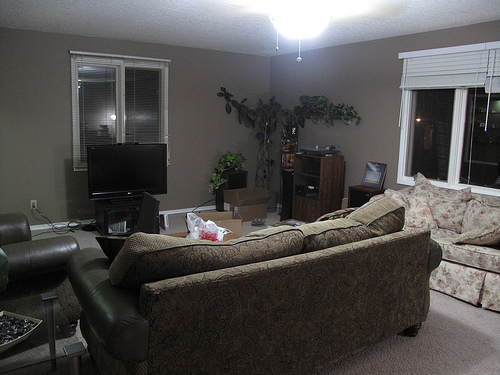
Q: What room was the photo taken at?
A: It was taken at the living room.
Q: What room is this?
A: It is a living room.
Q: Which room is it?
A: It is a living room.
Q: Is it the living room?
A: Yes, it is the living room.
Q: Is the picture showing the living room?
A: Yes, it is showing the living room.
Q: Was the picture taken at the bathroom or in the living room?
A: It was taken at the living room.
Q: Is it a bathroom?
A: No, it is a living room.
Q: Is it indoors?
A: Yes, it is indoors.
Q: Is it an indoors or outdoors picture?
A: It is indoors.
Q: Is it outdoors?
A: No, it is indoors.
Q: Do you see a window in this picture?
A: Yes, there is a window.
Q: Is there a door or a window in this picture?
A: Yes, there is a window.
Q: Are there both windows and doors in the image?
A: No, there is a window but no doors.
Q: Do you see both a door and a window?
A: No, there is a window but no doors.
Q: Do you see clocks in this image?
A: No, there are no clocks.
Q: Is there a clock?
A: No, there are no clocks.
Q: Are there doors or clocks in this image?
A: No, there are no clocks or doors.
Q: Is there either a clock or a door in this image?
A: No, there are no clocks or doors.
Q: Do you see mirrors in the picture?
A: No, there are no mirrors.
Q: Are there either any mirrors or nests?
A: No, there are no mirrors or nests.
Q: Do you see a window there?
A: Yes, there is a window.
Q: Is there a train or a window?
A: Yes, there is a window.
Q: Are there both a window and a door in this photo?
A: No, there is a window but no doors.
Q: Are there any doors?
A: No, there are no doors.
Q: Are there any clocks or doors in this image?
A: No, there are no doors or clocks.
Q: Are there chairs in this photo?
A: Yes, there is a chair.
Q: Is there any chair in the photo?
A: Yes, there is a chair.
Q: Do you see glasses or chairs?
A: Yes, there is a chair.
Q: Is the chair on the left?
A: Yes, the chair is on the left of the image.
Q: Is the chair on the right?
A: No, the chair is on the left of the image.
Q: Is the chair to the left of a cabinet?
A: No, the chair is to the left of a box.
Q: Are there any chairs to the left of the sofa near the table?
A: Yes, there is a chair to the left of the sofa.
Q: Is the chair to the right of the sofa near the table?
A: No, the chair is to the left of the sofa.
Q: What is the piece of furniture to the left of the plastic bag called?
A: The piece of furniture is a chair.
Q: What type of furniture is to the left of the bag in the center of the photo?
A: The piece of furniture is a chair.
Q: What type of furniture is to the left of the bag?
A: The piece of furniture is a chair.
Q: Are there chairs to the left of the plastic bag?
A: Yes, there is a chair to the left of the bag.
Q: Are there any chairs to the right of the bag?
A: No, the chair is to the left of the bag.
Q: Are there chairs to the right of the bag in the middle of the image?
A: No, the chair is to the left of the bag.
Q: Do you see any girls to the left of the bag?
A: No, there is a chair to the left of the bag.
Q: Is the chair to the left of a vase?
A: No, the chair is to the left of the bag.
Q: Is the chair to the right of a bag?
A: No, the chair is to the left of a bag.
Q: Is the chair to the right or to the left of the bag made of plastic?
A: The chair is to the left of the bag.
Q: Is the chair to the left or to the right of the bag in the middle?
A: The chair is to the left of the bag.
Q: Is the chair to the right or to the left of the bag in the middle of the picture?
A: The chair is to the left of the bag.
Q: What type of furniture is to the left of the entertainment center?
A: The piece of furniture is a chair.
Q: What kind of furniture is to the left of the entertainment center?
A: The piece of furniture is a chair.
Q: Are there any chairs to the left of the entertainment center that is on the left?
A: Yes, there is a chair to the left of the entertainment center.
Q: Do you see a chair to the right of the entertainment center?
A: No, the chair is to the left of the entertainment center.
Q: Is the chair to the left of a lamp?
A: No, the chair is to the left of the entertainment center.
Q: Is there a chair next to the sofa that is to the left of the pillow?
A: Yes, there is a chair next to the sofa.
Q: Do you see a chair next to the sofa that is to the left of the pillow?
A: Yes, there is a chair next to the sofa.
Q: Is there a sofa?
A: Yes, there is a sofa.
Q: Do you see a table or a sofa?
A: Yes, there is a sofa.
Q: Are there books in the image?
A: No, there are no books.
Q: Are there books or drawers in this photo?
A: No, there are no books or drawers.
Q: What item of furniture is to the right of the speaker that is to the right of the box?
A: The piece of furniture is a sofa.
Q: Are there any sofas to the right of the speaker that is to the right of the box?
A: Yes, there is a sofa to the right of the speaker.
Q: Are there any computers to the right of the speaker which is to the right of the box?
A: No, there is a sofa to the right of the speaker.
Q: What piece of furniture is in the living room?
A: The piece of furniture is a sofa.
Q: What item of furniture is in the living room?
A: The piece of furniture is a sofa.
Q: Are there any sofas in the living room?
A: Yes, there is a sofa in the living room.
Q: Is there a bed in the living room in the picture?
A: No, there is a sofa in the living room.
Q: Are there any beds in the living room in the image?
A: No, there is a sofa in the living room.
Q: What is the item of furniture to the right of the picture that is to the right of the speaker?
A: The piece of furniture is a sofa.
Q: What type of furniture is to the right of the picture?
A: The piece of furniture is a sofa.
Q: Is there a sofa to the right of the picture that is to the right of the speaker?
A: Yes, there is a sofa to the right of the picture.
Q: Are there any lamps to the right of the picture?
A: No, there is a sofa to the right of the picture.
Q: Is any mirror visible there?
A: No, there are no mirrors.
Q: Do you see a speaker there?
A: Yes, there is a speaker.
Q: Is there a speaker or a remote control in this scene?
A: Yes, there is a speaker.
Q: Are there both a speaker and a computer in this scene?
A: No, there is a speaker but no computers.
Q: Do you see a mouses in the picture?
A: No, there are no computer mousess.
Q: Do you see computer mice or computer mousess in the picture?
A: No, there are no computer mousess or computer mice.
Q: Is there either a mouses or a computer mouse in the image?
A: No, there are no computer mousess or computer mice.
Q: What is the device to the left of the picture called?
A: The device is a speaker.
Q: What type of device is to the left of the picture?
A: The device is a speaker.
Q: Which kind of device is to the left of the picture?
A: The device is a speaker.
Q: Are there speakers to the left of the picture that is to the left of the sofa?
A: Yes, there is a speaker to the left of the picture.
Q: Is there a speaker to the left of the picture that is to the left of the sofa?
A: Yes, there is a speaker to the left of the picture.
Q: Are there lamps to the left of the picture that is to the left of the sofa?
A: No, there is a speaker to the left of the picture.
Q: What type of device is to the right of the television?
A: The device is a speaker.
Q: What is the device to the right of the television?
A: The device is a speaker.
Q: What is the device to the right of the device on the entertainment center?
A: The device is a speaker.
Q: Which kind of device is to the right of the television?
A: The device is a speaker.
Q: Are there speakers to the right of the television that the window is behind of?
A: Yes, there is a speaker to the right of the TV.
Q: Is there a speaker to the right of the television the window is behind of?
A: Yes, there is a speaker to the right of the TV.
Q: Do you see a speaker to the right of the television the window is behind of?
A: Yes, there is a speaker to the right of the TV.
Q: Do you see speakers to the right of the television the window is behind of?
A: Yes, there is a speaker to the right of the TV.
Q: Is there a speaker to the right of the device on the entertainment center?
A: Yes, there is a speaker to the right of the TV.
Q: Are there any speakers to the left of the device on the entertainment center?
A: No, the speaker is to the right of the television.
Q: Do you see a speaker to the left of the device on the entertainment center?
A: No, the speaker is to the right of the television.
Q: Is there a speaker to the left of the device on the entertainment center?
A: No, the speaker is to the right of the television.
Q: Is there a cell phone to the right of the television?
A: No, there is a speaker to the right of the television.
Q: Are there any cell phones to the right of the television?
A: No, there is a speaker to the right of the television.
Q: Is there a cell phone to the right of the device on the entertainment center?
A: No, there is a speaker to the right of the television.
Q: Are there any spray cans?
A: No, there are no spray cans.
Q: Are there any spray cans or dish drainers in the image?
A: No, there are no spray cans or dish drainers.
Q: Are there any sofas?
A: Yes, there is a sofa.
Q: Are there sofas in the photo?
A: Yes, there is a sofa.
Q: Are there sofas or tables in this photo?
A: Yes, there is a sofa.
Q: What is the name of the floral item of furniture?
A: The piece of furniture is a sofa.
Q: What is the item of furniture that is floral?
A: The piece of furniture is a sofa.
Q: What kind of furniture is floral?
A: The furniture is a sofa.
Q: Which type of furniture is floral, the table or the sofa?
A: The sofa is floral.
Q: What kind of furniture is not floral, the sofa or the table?
A: The table is not floral.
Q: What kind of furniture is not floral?
A: The furniture is a table.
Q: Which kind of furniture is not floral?
A: The furniture is a table.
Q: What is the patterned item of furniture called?
A: The piece of furniture is a sofa.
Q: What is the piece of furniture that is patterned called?
A: The piece of furniture is a sofa.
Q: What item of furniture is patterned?
A: The piece of furniture is a sofa.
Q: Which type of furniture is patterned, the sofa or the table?
A: The sofa is patterned.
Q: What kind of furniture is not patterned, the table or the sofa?
A: The table is not patterned.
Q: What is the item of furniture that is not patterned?
A: The piece of furniture is a table.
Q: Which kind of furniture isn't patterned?
A: The furniture is a table.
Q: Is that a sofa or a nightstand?
A: That is a sofa.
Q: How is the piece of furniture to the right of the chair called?
A: The piece of furniture is a sofa.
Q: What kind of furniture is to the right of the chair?
A: The piece of furniture is a sofa.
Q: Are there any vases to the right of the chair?
A: No, there is a sofa to the right of the chair.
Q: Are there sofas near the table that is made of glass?
A: Yes, there is a sofa near the table.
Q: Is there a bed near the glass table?
A: No, there is a sofa near the table.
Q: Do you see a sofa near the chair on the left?
A: Yes, there is a sofa near the chair.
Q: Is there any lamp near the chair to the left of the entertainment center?
A: No, there is a sofa near the chair.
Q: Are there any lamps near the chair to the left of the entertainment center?
A: No, there is a sofa near the chair.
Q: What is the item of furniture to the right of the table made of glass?
A: The piece of furniture is a sofa.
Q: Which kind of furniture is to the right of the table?
A: The piece of furniture is a sofa.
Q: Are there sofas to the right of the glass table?
A: Yes, there is a sofa to the right of the table.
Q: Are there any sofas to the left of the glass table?
A: No, the sofa is to the right of the table.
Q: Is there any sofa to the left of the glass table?
A: No, the sofa is to the right of the table.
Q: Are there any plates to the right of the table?
A: No, there is a sofa to the right of the table.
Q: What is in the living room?
A: The sofa is in the living room.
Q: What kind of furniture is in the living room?
A: The piece of furniture is a sofa.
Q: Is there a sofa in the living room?
A: Yes, there is a sofa in the living room.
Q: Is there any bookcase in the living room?
A: No, there is a sofa in the living room.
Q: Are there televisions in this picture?
A: Yes, there is a television.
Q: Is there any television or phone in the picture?
A: Yes, there is a television.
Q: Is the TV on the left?
A: Yes, the TV is on the left of the image.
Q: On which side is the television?
A: The television is on the left of the image.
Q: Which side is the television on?
A: The television is on the left of the image.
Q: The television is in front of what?
A: The television is in front of the window.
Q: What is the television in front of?
A: The television is in front of the window.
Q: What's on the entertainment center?
A: The TV is on the entertainment center.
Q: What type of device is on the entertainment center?
A: The device is a television.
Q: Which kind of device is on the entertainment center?
A: The device is a television.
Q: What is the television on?
A: The television is on the entertainment center.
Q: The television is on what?
A: The television is on the entertainment center.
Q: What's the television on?
A: The television is on the entertainment center.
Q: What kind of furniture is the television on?
A: The television is on the entertainment center.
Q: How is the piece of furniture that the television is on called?
A: The piece of furniture is an entertainment center.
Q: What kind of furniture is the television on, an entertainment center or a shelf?
A: The television is on an entertainment center.